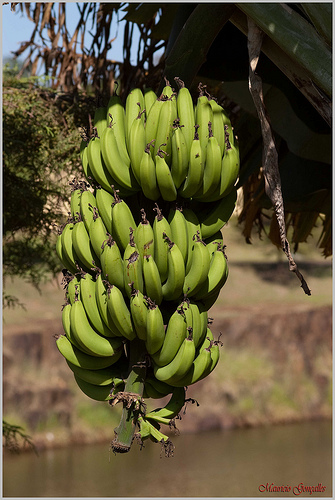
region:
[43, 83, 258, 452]
a bunch of bananas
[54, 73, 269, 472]
bananas hanging from a plant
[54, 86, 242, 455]
the bananas are slightly green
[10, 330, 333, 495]
background is blurry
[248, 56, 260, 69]
small spot of light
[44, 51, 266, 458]
bananas that are growing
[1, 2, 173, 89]
blue sky with no clouds in sight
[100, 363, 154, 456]
dark green stem coming out of the bananas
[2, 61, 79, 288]
greenery by the bananas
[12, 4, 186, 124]
leaves hanging down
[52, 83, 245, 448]
green bananas in a bunch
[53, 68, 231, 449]
a bunch of green bananas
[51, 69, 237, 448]
bananas hanging on a tree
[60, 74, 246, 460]
a bunch of bananas hanging on a tree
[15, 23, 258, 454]
bananas growing on a tree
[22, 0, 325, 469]
a banana tree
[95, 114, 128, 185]
a green banana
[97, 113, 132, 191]
a green banana in a bunch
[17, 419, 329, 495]
water below the bananas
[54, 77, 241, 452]
Bunch of green bananas handing from a tree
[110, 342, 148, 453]
Stem of a bunch of green bananas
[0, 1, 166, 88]
Blue sky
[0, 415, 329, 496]
Muddy river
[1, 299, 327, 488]
Muddy river with a steep bank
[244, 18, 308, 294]
Long, thin, dead leaf hanging down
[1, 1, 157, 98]
Many long, thin, dead leaves hanging down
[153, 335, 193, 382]
A green banana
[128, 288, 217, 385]
A bunch of green bananas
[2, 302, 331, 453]
Steep river bank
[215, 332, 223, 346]
a dry brown stem on a banana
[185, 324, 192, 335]
a dry brown stem on a banana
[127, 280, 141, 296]
a dry brown stem on a banana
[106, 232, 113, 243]
a dry brown stem on a banana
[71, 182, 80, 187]
a dry brown stem on a banana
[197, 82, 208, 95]
a dry brown stem on a banana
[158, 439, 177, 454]
a dry brown stem on a banana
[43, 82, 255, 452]
a large bunch of green bananas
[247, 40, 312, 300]
a long dried leaf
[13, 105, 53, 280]
small green leaves covering a tree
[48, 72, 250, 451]
Green bananas hanging from tree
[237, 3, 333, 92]
Leaves of the banana tree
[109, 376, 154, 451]
End stalk of the bunch of bananas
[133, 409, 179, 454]
Some bananas have been taken off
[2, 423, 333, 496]
Bananas are hanging over water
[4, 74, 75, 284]
Green bush to the left of the hanging bananas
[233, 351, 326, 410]
Green bushes growing along the side of the river bank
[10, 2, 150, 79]
Leaves of the banana tree are brown and burnt on the left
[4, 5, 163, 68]
Blue sky in the distance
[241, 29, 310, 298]
One dead leaf on the right side of the bananas